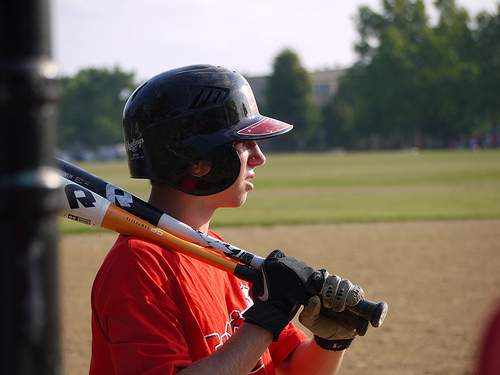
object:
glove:
[243, 251, 323, 341]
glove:
[304, 266, 359, 341]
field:
[57, 147, 499, 224]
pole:
[0, 0, 51, 375]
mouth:
[242, 175, 260, 189]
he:
[91, 62, 370, 372]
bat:
[57, 174, 369, 336]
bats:
[37, 160, 417, 337]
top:
[88, 252, 199, 372]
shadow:
[130, 122, 190, 228]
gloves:
[216, 252, 406, 346]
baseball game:
[38, 39, 419, 365]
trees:
[344, 23, 492, 144]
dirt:
[57, 217, 497, 373]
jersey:
[98, 235, 241, 360]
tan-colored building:
[301, 62, 358, 112]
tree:
[56, 64, 138, 147]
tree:
[261, 46, 318, 152]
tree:
[336, 59, 391, 150]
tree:
[379, 0, 479, 150]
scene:
[10, 14, 495, 365]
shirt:
[78, 225, 314, 374]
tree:
[55, 55, 134, 154]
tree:
[431, 13, 484, 143]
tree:
[377, 14, 426, 144]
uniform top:
[88, 223, 313, 373]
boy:
[67, 55, 354, 365]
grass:
[268, 162, 495, 212]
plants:
[41, 0, 498, 235]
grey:
[318, 272, 363, 319]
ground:
[60, 216, 499, 373]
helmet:
[121, 61, 303, 203]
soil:
[233, 159, 498, 221]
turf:
[240, 227, 488, 315]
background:
[162, 104, 494, 307]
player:
[82, 62, 366, 373]